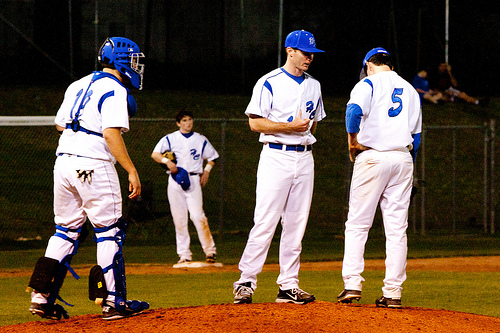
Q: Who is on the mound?
A: Pitcher.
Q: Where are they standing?
A: On the field.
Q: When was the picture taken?
A: Nighttime.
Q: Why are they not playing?
A: It is a time out.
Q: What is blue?
A: Hats.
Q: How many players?
A: Four.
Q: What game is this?
A: Baseball.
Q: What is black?
A: Catchers pads.